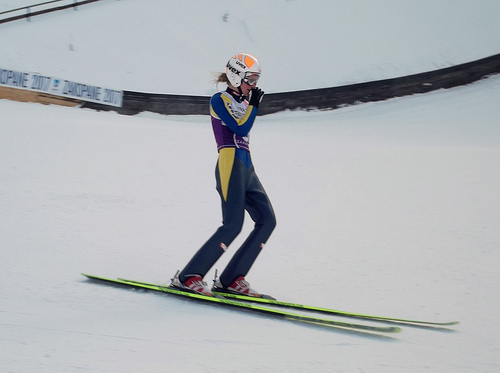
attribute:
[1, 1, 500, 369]
snow — smooth, white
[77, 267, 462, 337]
skis — yellow, black, neon green, green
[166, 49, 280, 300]
person — woman, skier, standing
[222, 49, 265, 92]
helmet — orange, white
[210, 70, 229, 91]
hair — hanging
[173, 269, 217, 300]
shoe — red, white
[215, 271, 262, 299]
shoe — red, white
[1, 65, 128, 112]
sign — posted, white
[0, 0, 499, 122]
gate — black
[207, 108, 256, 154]
top — purple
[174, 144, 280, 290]
pants — yellow, black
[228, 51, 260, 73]
shape — orange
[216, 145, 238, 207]
triangle — yellow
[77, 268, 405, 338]
ski — yellow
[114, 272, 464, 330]
ski — yellow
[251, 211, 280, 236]
knee — bent